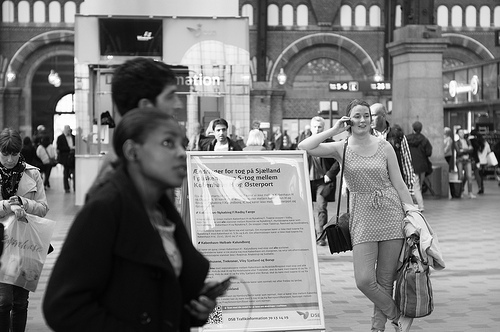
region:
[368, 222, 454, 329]
woman holding striped purse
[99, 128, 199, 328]
woman looking at something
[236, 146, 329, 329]
a large white sign with black letters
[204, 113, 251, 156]
man wearing white shirt and dark jacket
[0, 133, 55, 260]
woman holding a bag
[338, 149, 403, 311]
shirt tied in front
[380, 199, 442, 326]
person holding a coat and bag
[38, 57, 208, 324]
two people looking different directions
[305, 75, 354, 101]
white numbers that say 5-6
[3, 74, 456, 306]
people at a train station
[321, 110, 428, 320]
woman leaning on folding sign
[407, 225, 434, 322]
woman holding striped bag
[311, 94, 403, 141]
woman talking on cell phone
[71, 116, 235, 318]
lady with dark jacket looking up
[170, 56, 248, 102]
part of sign reading information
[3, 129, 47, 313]
woman with light jacket walking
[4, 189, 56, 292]
woman carries white plastic sack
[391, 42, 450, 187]
big stone and mortar pillar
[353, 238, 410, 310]
woman's legs are crossed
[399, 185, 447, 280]
woman with jacket hanging on arm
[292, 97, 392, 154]
a woman talking on a cell phone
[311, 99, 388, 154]
a woman holding a cell phone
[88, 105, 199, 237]
a woman looking up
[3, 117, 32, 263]
a woman looking at her watch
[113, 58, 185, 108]
a man with black hair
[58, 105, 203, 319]
a woman wearing a black jacket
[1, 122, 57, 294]
a woman holding a plastic bag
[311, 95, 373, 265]
a woman with a bag on her shoulder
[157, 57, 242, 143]
a information booth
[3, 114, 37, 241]
a woman looking down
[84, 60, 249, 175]
information booth in the background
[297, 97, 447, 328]
a lady standing with legs crossed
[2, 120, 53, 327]
a woman holding a shopping bag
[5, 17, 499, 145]
stone arches in the background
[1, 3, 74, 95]
three lit ceiling lights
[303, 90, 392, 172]
a lady talking on her cell phone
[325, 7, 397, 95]
a hanging building directional sign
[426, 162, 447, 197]
trash receptacle next to the stone pillar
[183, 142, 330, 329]
large framed informational sign standing off the floor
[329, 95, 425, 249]
lady wearing a long polka dot tank top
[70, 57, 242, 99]
information counter at train station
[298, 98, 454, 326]
woman on phone with luggage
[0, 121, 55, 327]
woman with shopping bag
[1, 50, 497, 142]
at a train station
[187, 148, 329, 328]
information sign on ground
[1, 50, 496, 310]
black and white picture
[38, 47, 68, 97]
lights hanging from ceiling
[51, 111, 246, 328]
listening to music from phone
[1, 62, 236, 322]
people wearing coats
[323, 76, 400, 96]
sign telling train terminals